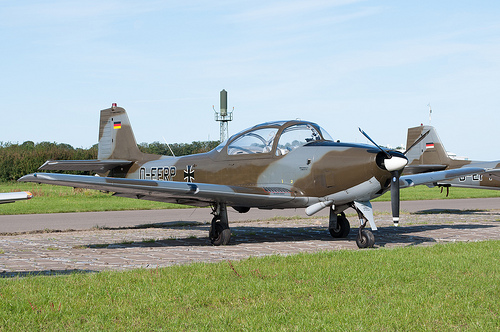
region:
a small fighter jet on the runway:
[29, 77, 444, 249]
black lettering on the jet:
[129, 165, 204, 189]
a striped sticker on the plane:
[104, 117, 131, 130]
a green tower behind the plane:
[211, 80, 241, 125]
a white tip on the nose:
[390, 152, 411, 174]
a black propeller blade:
[393, 173, 401, 228]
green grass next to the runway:
[309, 270, 393, 323]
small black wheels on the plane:
[353, 230, 382, 246]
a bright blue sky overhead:
[291, 25, 431, 87]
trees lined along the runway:
[6, 135, 68, 165]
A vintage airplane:
[26, 89, 445, 229]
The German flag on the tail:
[106, 112, 128, 136]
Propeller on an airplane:
[357, 110, 433, 226]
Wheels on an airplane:
[180, 188, 395, 264]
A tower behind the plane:
[207, 76, 244, 161]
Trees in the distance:
[8, 117, 264, 195]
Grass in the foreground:
[48, 236, 483, 317]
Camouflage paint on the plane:
[91, 107, 376, 193]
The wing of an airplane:
[25, 160, 310, 210]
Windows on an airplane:
[218, 100, 335, 163]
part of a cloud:
[253, 14, 295, 61]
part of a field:
[273, 267, 316, 313]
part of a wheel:
[361, 230, 375, 244]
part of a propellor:
[382, 187, 412, 226]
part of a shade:
[168, 230, 188, 243]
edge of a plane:
[270, 144, 327, 209]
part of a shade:
[155, 216, 185, 249]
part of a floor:
[58, 228, 100, 267]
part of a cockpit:
[254, 90, 289, 167]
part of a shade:
[148, 228, 185, 260]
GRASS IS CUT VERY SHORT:
[186, 282, 223, 314]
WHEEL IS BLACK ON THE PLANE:
[371, 239, 373, 244]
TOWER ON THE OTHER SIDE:
[215, 87, 230, 138]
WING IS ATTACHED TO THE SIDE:
[127, 184, 179, 189]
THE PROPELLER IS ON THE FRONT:
[392, 191, 396, 215]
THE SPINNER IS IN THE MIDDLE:
[388, 152, 401, 169]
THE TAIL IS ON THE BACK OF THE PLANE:
[107, 134, 124, 154]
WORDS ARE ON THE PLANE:
[140, 166, 181, 181]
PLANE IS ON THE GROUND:
[61, 96, 406, 246]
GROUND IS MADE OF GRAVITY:
[39, 242, 100, 254]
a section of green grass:
[0, 238, 497, 330]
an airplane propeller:
[355, 124, 445, 226]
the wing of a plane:
[17, 168, 312, 220]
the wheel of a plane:
[354, 227, 377, 249]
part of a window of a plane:
[220, 125, 279, 154]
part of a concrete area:
[2, 207, 499, 272]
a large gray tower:
[210, 85, 241, 147]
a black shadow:
[410, 205, 485, 217]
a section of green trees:
[0, 140, 102, 179]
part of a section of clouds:
[223, 0, 383, 37]